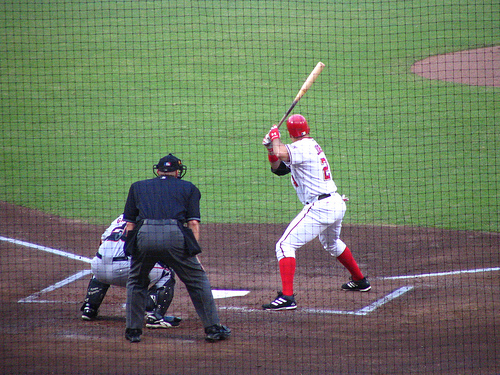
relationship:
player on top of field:
[262, 113, 373, 311] [0, 3, 499, 371]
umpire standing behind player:
[121, 151, 231, 349] [262, 113, 373, 311]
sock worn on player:
[275, 255, 297, 296] [262, 113, 373, 311]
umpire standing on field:
[121, 151, 231, 349] [0, 3, 499, 371]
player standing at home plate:
[262, 113, 373, 311] [211, 285, 252, 304]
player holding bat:
[262, 113, 373, 311] [261, 60, 327, 148]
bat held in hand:
[261, 60, 327, 148] [267, 119, 280, 137]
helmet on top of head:
[284, 113, 313, 140] [284, 110, 314, 146]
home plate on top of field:
[211, 285, 252, 304] [0, 3, 499, 371]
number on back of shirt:
[317, 156, 333, 184] [285, 137, 340, 203]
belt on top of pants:
[314, 190, 334, 202] [274, 197, 348, 263]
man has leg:
[77, 209, 184, 331] [118, 258, 180, 332]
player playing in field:
[262, 113, 373, 311] [0, 3, 499, 371]